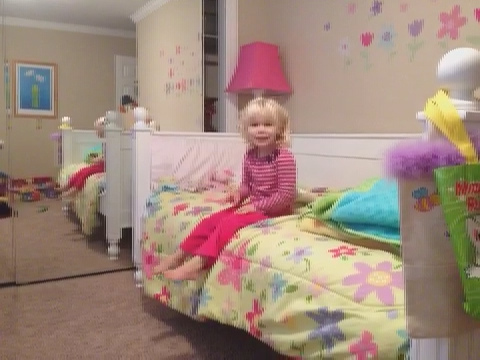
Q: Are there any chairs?
A: No, there are no chairs.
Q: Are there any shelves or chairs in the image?
A: No, there are no chairs or shelves.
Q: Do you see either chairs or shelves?
A: No, there are no chairs or shelves.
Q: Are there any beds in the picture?
A: Yes, there is a bed.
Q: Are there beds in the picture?
A: Yes, there is a bed.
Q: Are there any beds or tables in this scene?
A: Yes, there is a bed.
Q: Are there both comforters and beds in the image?
A: Yes, there are both a bed and a comforter.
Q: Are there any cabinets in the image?
A: No, there are no cabinets.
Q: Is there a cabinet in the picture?
A: No, there are no cabinets.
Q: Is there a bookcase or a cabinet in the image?
A: No, there are no cabinets or bookcases.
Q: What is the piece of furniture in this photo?
A: The piece of furniture is a bed.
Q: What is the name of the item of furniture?
A: The piece of furniture is a bed.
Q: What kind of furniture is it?
A: The piece of furniture is a bed.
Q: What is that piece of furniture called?
A: This is a bed.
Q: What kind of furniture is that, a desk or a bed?
A: This is a bed.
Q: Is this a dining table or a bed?
A: This is a bed.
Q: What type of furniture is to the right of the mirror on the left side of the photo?
A: The piece of furniture is a bed.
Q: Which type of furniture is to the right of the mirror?
A: The piece of furniture is a bed.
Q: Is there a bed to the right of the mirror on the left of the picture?
A: Yes, there is a bed to the right of the mirror.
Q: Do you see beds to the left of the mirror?
A: No, the bed is to the right of the mirror.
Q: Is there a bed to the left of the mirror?
A: No, the bed is to the right of the mirror.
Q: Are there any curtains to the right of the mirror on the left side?
A: No, there is a bed to the right of the mirror.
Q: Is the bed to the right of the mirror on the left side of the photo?
A: Yes, the bed is to the right of the mirror.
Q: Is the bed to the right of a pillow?
A: No, the bed is to the right of the mirror.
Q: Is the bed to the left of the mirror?
A: No, the bed is to the right of the mirror.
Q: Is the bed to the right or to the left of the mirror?
A: The bed is to the right of the mirror.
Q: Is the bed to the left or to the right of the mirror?
A: The bed is to the right of the mirror.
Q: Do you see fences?
A: No, there are no fences.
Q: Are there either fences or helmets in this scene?
A: No, there are no fences or helmets.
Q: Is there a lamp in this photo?
A: Yes, there is a lamp.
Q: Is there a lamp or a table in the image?
A: Yes, there is a lamp.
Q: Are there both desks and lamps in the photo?
A: No, there is a lamp but no desks.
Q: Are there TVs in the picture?
A: No, there are no tvs.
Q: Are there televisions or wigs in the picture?
A: No, there are no televisions or wigs.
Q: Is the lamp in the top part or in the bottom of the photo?
A: The lamp is in the top of the image.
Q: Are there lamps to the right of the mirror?
A: Yes, there is a lamp to the right of the mirror.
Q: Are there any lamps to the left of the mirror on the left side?
A: No, the lamp is to the right of the mirror.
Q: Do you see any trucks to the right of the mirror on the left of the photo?
A: No, there is a lamp to the right of the mirror.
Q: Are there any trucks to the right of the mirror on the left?
A: No, there is a lamp to the right of the mirror.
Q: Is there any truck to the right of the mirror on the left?
A: No, there is a lamp to the right of the mirror.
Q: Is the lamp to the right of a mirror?
A: Yes, the lamp is to the right of a mirror.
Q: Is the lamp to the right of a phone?
A: No, the lamp is to the right of a mirror.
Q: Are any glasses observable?
A: No, there are no glasses.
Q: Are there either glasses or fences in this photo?
A: No, there are no glasses or fences.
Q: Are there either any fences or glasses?
A: No, there are no glasses or fences.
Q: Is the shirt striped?
A: Yes, the shirt is striped.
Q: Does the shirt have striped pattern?
A: Yes, the shirt is striped.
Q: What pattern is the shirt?
A: The shirt is striped.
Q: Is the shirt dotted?
A: No, the shirt is striped.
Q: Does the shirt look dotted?
A: No, the shirt is striped.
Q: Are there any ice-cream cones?
A: No, there are no ice-cream cones.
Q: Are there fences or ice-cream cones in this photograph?
A: No, there are no ice-cream cones or fences.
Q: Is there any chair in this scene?
A: No, there are no chairs.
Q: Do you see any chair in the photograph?
A: No, there are no chairs.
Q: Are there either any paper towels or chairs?
A: No, there are no chairs or paper towels.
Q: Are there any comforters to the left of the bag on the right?
A: Yes, there is a comforter to the left of the bag.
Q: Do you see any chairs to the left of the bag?
A: No, there is a comforter to the left of the bag.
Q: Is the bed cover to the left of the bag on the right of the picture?
A: Yes, the bed cover is to the left of the bag.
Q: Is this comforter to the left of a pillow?
A: No, the comforter is to the left of the bag.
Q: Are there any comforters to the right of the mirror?
A: Yes, there is a comforter to the right of the mirror.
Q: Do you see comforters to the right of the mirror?
A: Yes, there is a comforter to the right of the mirror.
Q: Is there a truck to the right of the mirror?
A: No, there is a comforter to the right of the mirror.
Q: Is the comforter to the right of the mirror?
A: Yes, the comforter is to the right of the mirror.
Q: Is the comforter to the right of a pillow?
A: No, the comforter is to the right of the mirror.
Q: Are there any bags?
A: Yes, there is a bag.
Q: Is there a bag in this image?
A: Yes, there is a bag.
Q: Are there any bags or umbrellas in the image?
A: Yes, there is a bag.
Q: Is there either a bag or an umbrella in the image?
A: Yes, there is a bag.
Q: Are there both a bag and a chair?
A: No, there is a bag but no chairs.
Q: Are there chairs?
A: No, there are no chairs.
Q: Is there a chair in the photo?
A: No, there are no chairs.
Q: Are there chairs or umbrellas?
A: No, there are no chairs or umbrellas.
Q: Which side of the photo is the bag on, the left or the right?
A: The bag is on the right of the image.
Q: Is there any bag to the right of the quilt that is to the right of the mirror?
A: Yes, there is a bag to the right of the comforter.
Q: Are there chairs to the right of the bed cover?
A: No, there is a bag to the right of the bed cover.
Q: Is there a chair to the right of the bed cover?
A: No, there is a bag to the right of the bed cover.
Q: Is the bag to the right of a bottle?
A: No, the bag is to the right of the comforter.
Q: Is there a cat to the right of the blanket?
A: No, there is a bag to the right of the blanket.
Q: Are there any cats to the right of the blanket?
A: No, there is a bag to the right of the blanket.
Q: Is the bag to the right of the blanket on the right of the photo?
A: Yes, the bag is to the right of the blanket.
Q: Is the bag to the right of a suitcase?
A: No, the bag is to the right of the blanket.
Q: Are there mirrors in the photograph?
A: Yes, there is a mirror.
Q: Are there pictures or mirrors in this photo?
A: Yes, there is a mirror.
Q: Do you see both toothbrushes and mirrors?
A: No, there is a mirror but no toothbrushes.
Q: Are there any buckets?
A: No, there are no buckets.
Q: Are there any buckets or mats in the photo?
A: No, there are no buckets or mats.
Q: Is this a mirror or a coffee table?
A: This is a mirror.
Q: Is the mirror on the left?
A: Yes, the mirror is on the left of the image.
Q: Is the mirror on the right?
A: No, the mirror is on the left of the image.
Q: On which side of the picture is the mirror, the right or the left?
A: The mirror is on the left of the image.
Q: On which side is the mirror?
A: The mirror is on the left of the image.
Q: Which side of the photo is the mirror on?
A: The mirror is on the left of the image.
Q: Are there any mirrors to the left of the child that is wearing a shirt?
A: Yes, there is a mirror to the left of the kid.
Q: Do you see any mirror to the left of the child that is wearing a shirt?
A: Yes, there is a mirror to the left of the kid.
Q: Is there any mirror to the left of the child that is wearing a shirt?
A: Yes, there is a mirror to the left of the kid.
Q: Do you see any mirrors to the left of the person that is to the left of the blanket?
A: Yes, there is a mirror to the left of the kid.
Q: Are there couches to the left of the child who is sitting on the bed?
A: No, there is a mirror to the left of the child.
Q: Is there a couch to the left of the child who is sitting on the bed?
A: No, there is a mirror to the left of the child.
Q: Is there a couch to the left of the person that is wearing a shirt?
A: No, there is a mirror to the left of the child.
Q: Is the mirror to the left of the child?
A: Yes, the mirror is to the left of the child.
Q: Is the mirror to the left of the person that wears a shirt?
A: Yes, the mirror is to the left of the child.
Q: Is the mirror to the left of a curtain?
A: No, the mirror is to the left of the child.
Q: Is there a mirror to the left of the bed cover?
A: Yes, there is a mirror to the left of the bed cover.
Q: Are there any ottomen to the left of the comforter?
A: No, there is a mirror to the left of the comforter.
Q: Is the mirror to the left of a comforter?
A: Yes, the mirror is to the left of a comforter.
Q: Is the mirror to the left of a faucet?
A: No, the mirror is to the left of a comforter.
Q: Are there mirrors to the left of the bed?
A: Yes, there is a mirror to the left of the bed.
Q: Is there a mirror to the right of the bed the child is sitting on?
A: No, the mirror is to the left of the bed.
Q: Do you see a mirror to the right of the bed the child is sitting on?
A: No, the mirror is to the left of the bed.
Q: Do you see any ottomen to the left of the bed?
A: No, there is a mirror to the left of the bed.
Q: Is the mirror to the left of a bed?
A: Yes, the mirror is to the left of a bed.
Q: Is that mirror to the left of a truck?
A: No, the mirror is to the left of a bed.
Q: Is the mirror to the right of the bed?
A: No, the mirror is to the left of the bed.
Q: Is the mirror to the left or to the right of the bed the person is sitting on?
A: The mirror is to the left of the bed.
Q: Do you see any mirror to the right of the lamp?
A: No, the mirror is to the left of the lamp.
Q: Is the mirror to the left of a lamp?
A: Yes, the mirror is to the left of a lamp.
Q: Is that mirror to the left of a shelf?
A: No, the mirror is to the left of a lamp.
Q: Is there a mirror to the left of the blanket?
A: Yes, there is a mirror to the left of the blanket.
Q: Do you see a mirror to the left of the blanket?
A: Yes, there is a mirror to the left of the blanket.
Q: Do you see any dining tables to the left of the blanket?
A: No, there is a mirror to the left of the blanket.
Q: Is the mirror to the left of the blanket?
A: Yes, the mirror is to the left of the blanket.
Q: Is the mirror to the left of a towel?
A: No, the mirror is to the left of the blanket.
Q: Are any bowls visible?
A: No, there are no bowls.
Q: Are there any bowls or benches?
A: No, there are no bowls or benches.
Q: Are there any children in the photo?
A: Yes, there is a child.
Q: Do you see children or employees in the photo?
A: Yes, there is a child.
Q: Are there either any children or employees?
A: Yes, there is a child.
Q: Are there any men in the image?
A: No, there are no men.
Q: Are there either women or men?
A: No, there are no men or women.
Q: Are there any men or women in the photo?
A: No, there are no men or women.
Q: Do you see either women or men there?
A: No, there are no men or women.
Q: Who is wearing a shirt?
A: The child is wearing a shirt.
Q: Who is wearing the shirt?
A: The child is wearing a shirt.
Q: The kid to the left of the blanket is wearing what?
A: The child is wearing a shirt.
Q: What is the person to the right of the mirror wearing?
A: The child is wearing a shirt.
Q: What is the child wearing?
A: The child is wearing a shirt.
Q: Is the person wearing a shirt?
A: Yes, the child is wearing a shirt.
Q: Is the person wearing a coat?
A: No, the kid is wearing a shirt.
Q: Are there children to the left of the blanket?
A: Yes, there is a child to the left of the blanket.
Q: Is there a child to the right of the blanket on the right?
A: No, the child is to the left of the blanket.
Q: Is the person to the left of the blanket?
A: Yes, the child is to the left of the blanket.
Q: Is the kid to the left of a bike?
A: No, the kid is to the left of the blanket.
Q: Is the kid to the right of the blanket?
A: No, the kid is to the left of the blanket.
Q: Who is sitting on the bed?
A: The kid is sitting on the bed.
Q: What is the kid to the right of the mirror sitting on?
A: The child is sitting on the bed.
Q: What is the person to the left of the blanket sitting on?
A: The child is sitting on the bed.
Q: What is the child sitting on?
A: The child is sitting on the bed.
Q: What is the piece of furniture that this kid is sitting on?
A: The piece of furniture is a bed.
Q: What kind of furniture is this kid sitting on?
A: The kid is sitting on the bed.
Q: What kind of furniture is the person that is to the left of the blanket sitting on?
A: The kid is sitting on the bed.